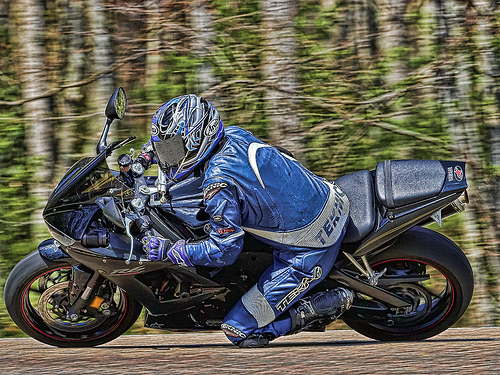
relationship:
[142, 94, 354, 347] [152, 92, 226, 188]
rider wearing helmet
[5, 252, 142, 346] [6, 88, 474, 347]
wheel of motorcycle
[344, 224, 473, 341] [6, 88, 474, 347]
wheel of motorcycle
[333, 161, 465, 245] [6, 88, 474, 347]
seat of motorcycle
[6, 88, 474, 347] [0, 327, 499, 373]
motorcycle on road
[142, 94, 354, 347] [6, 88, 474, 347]
person riding motorcycle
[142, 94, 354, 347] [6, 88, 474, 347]
rider with motorcycle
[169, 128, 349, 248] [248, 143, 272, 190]
jacket has logo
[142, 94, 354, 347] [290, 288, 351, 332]
rider wearing boot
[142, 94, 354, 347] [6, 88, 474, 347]
rider on motorcycle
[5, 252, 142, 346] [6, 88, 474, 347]
wheel on motorcycle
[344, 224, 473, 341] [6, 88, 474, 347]
wheel on motorcycle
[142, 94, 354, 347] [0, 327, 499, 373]
rider near road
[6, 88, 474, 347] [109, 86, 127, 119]
motorcycle has mirror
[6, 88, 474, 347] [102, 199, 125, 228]
motorcycle has mirror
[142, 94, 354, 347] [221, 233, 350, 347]
rider wearing pants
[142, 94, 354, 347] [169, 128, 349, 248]
rider wearing jacket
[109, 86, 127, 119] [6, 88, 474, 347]
mirror on motorcycle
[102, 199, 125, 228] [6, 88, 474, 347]
mirror on motorcycle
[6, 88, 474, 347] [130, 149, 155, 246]
motorcycle has handlebars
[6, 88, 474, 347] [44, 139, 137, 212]
motorcycle has windshield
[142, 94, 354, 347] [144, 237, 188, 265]
rider wearing gloves